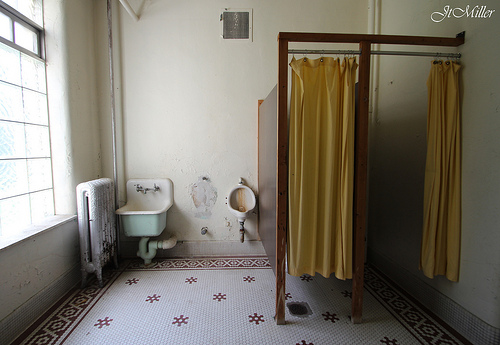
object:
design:
[167, 308, 194, 328]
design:
[145, 292, 166, 305]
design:
[214, 290, 227, 302]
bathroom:
[1, 0, 500, 344]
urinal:
[226, 179, 259, 242]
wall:
[96, 3, 371, 260]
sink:
[115, 179, 176, 264]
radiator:
[76, 176, 122, 286]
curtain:
[289, 53, 351, 280]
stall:
[253, 31, 474, 329]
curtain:
[421, 53, 461, 281]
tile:
[8, 256, 480, 344]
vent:
[220, 11, 253, 42]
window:
[1, 1, 51, 63]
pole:
[106, 2, 123, 268]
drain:
[286, 297, 313, 317]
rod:
[281, 48, 460, 58]